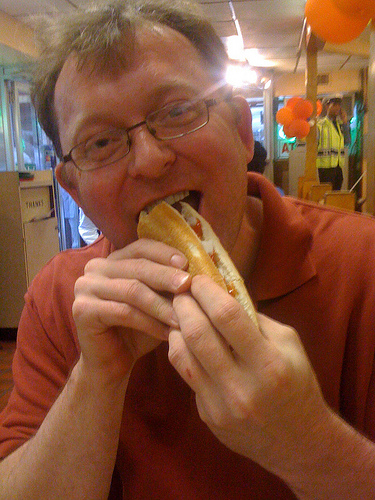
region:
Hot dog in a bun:
[129, 199, 259, 339]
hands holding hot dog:
[70, 201, 328, 427]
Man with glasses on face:
[57, 90, 230, 174]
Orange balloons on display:
[275, 94, 322, 139]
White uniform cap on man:
[319, 90, 345, 107]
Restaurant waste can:
[4, 166, 59, 334]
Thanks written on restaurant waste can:
[21, 196, 49, 211]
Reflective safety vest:
[314, 117, 347, 172]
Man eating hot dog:
[22, 6, 267, 345]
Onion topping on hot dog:
[197, 239, 219, 256]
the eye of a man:
[138, 92, 219, 141]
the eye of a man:
[73, 122, 138, 170]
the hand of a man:
[163, 272, 373, 494]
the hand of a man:
[0, 236, 192, 499]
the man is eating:
[11, 0, 370, 494]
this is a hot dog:
[118, 193, 267, 338]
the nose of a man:
[123, 141, 180, 186]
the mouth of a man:
[131, 180, 215, 240]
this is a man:
[308, 79, 368, 200]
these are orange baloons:
[260, 76, 326, 160]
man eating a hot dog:
[4, 8, 373, 498]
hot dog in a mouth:
[109, 173, 276, 362]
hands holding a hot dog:
[58, 198, 326, 441]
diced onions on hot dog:
[176, 202, 237, 281]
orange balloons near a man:
[270, 83, 355, 188]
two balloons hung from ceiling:
[270, 1, 372, 211]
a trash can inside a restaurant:
[0, 53, 101, 338]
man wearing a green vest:
[305, 90, 356, 195]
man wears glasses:
[15, 6, 333, 338]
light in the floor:
[211, 24, 289, 109]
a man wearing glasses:
[44, 113, 212, 194]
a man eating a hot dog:
[112, 114, 239, 282]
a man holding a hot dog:
[77, 166, 244, 491]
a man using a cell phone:
[321, 92, 351, 136]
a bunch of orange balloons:
[270, 92, 320, 150]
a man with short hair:
[28, 20, 233, 145]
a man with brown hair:
[41, 16, 212, 139]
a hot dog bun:
[147, 215, 241, 285]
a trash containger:
[15, 166, 55, 287]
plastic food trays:
[7, 164, 55, 191]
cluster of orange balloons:
[272, 96, 321, 142]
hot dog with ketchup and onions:
[135, 201, 259, 350]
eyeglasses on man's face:
[55, 84, 235, 175]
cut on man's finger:
[184, 364, 194, 381]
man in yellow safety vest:
[314, 91, 347, 193]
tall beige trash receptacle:
[1, 166, 62, 337]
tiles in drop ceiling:
[213, 3, 357, 69]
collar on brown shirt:
[246, 172, 316, 305]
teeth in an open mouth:
[130, 188, 191, 211]